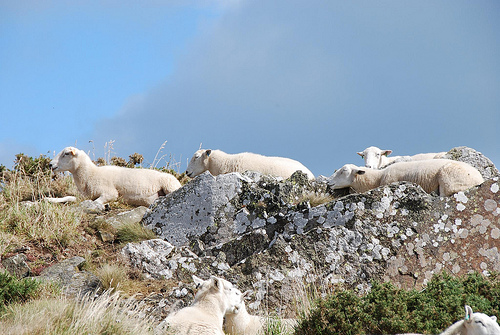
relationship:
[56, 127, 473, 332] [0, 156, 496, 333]
sheep on hillside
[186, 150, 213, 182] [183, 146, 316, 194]
head of sheep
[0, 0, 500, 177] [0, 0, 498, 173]
cloud in sky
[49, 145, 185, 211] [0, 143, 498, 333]
sheep on hill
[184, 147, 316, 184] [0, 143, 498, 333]
sheep on hill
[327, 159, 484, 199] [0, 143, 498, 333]
sheep on hill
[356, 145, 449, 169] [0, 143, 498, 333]
sheep on hill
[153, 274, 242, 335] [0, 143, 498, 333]
sheep on hill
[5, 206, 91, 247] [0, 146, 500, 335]
grass on hill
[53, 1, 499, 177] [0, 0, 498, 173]
cloud in sky